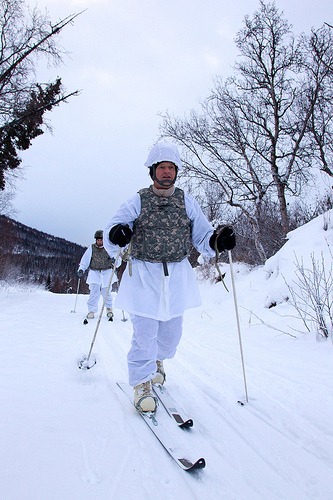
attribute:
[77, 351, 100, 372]
bottom — round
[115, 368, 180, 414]
shoes — tan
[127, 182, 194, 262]
vest — camouflage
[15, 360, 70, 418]
snow — white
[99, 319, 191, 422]
pants — white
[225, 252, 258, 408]
skipole — long, white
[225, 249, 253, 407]
pole — ski, long, white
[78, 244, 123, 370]
pole — white, long, ski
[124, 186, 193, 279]
vest — camo, protective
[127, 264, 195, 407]
jeans — frayed, blue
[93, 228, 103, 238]
helmet — camo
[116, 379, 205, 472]
ski — curved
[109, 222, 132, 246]
glove — black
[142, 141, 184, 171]
hat — white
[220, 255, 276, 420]
pole — metal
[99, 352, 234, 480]
skis — white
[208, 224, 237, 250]
glove — black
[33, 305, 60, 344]
snow — white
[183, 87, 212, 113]
wall — black, brown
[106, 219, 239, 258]
gloves — black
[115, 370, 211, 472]
skis — snow, white, black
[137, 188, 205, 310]
shirt — white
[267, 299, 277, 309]
hole — small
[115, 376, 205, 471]
skis — long, white, brown, black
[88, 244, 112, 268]
vest — white, camo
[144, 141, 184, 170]
cover — white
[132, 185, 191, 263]
vest — camo